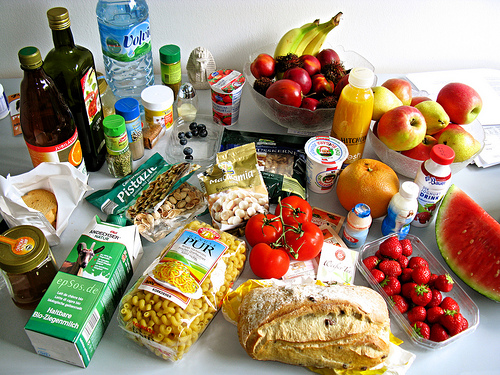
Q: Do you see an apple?
A: Yes, there is an apple.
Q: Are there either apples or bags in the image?
A: Yes, there is an apple.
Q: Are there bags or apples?
A: Yes, there is an apple.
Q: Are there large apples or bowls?
A: Yes, there is a large apple.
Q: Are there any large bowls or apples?
A: Yes, there is a large apple.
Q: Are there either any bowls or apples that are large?
A: Yes, the apple is large.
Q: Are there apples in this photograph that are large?
A: Yes, there is a large apple.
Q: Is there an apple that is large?
A: Yes, there is an apple that is large.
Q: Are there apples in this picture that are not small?
A: Yes, there is a large apple.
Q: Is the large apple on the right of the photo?
A: Yes, the apple is on the right of the image.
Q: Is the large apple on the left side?
A: No, the apple is on the right of the image.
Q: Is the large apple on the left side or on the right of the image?
A: The apple is on the right of the image.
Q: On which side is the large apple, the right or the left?
A: The apple is on the right of the image.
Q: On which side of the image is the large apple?
A: The apple is on the right of the image.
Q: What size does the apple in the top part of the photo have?
A: The apple has large size.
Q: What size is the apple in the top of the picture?
A: The apple is large.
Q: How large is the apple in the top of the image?
A: The apple is large.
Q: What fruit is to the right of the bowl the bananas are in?
A: The fruit is an apple.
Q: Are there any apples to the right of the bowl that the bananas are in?
A: Yes, there is an apple to the right of the bowl.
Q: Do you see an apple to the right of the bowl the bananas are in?
A: Yes, there is an apple to the right of the bowl.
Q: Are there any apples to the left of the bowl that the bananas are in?
A: No, the apple is to the right of the bowl.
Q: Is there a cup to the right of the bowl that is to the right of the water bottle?
A: No, there is an apple to the right of the bowl.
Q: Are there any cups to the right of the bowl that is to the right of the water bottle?
A: No, there is an apple to the right of the bowl.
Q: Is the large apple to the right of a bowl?
A: Yes, the apple is to the right of a bowl.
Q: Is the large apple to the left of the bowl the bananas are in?
A: No, the apple is to the right of the bowl.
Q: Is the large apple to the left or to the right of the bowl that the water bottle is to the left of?
A: The apple is to the right of the bowl.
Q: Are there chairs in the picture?
A: No, there are no chairs.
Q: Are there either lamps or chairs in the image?
A: No, there are no chairs or lamps.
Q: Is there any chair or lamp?
A: No, there are no chairs or lamps.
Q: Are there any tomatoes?
A: Yes, there are tomatoes.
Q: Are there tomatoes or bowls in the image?
A: Yes, there are tomatoes.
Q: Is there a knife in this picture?
A: No, there are no knives.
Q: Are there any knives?
A: No, there are no knives.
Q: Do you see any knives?
A: No, there are no knives.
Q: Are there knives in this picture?
A: No, there are no knives.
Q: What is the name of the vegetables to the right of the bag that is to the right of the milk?
A: The vegetables are tomatoes.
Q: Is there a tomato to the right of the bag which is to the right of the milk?
A: Yes, there are tomatoes to the right of the bag.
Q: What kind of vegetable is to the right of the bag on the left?
A: The vegetables are tomatoes.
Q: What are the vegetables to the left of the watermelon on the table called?
A: The vegetables are tomatoes.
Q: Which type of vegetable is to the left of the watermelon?
A: The vegetables are tomatoes.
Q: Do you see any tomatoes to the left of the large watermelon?
A: Yes, there are tomatoes to the left of the watermelon.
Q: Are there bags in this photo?
A: Yes, there is a bag.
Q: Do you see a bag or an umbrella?
A: Yes, there is a bag.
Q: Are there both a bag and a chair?
A: No, there is a bag but no chairs.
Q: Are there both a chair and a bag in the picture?
A: No, there is a bag but no chairs.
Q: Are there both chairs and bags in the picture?
A: No, there is a bag but no chairs.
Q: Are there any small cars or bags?
A: Yes, there is a small bag.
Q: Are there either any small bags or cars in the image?
A: Yes, there is a small bag.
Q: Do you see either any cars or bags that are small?
A: Yes, the bag is small.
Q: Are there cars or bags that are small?
A: Yes, the bag is small.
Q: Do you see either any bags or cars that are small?
A: Yes, the bag is small.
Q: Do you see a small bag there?
A: Yes, there is a small bag.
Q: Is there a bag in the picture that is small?
A: Yes, there is a bag that is small.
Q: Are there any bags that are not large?
A: Yes, there is a small bag.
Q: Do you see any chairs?
A: No, there are no chairs.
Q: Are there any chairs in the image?
A: No, there are no chairs.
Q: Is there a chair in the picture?
A: No, there are no chairs.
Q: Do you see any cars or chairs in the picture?
A: No, there are no chairs or cars.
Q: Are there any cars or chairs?
A: No, there are no chairs or cars.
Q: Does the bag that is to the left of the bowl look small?
A: Yes, the bag is small.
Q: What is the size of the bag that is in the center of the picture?
A: The bag is small.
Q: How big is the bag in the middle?
A: The bag is small.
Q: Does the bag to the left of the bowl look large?
A: No, the bag is small.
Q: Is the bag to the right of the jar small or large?
A: The bag is small.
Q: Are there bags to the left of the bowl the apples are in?
A: Yes, there is a bag to the left of the bowl.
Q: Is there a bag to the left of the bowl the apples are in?
A: Yes, there is a bag to the left of the bowl.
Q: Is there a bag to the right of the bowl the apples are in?
A: No, the bag is to the left of the bowl.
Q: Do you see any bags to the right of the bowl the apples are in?
A: No, the bag is to the left of the bowl.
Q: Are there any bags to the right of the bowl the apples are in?
A: No, the bag is to the left of the bowl.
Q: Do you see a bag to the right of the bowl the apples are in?
A: No, the bag is to the left of the bowl.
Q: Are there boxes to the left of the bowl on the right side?
A: No, there is a bag to the left of the bowl.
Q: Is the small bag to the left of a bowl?
A: Yes, the bag is to the left of a bowl.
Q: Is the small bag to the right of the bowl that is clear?
A: No, the bag is to the left of the bowl.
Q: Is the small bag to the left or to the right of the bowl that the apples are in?
A: The bag is to the left of the bowl.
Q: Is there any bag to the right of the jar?
A: Yes, there is a bag to the right of the jar.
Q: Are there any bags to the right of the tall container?
A: Yes, there is a bag to the right of the jar.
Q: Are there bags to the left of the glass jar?
A: No, the bag is to the right of the jar.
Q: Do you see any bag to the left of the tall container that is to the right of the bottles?
A: No, the bag is to the right of the jar.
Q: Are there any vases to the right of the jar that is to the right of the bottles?
A: No, there is a bag to the right of the jar.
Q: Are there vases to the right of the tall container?
A: No, there is a bag to the right of the jar.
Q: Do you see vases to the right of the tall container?
A: No, there is a bag to the right of the jar.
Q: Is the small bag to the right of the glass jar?
A: Yes, the bag is to the right of the jar.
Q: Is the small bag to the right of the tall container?
A: Yes, the bag is to the right of the jar.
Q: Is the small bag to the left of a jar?
A: No, the bag is to the right of a jar.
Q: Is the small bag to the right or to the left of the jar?
A: The bag is to the right of the jar.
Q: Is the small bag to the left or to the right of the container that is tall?
A: The bag is to the right of the jar.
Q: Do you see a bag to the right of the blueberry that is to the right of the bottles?
A: Yes, there is a bag to the right of the blueberry.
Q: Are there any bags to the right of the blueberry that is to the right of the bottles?
A: Yes, there is a bag to the right of the blueberry.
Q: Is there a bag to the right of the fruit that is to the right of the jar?
A: Yes, there is a bag to the right of the blueberry.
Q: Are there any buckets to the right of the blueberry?
A: No, there is a bag to the right of the blueberry.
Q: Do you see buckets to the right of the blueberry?
A: No, there is a bag to the right of the blueberry.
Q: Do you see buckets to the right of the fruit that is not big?
A: No, there is a bag to the right of the blueberry.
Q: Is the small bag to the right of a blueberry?
A: Yes, the bag is to the right of a blueberry.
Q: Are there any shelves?
A: No, there are no shelves.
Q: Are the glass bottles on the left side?
A: Yes, the bottles are on the left of the image.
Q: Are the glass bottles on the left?
A: Yes, the bottles are on the left of the image.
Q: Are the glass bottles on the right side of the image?
A: No, the bottles are on the left of the image.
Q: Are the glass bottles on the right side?
A: No, the bottles are on the left of the image.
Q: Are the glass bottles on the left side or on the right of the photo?
A: The bottles are on the left of the image.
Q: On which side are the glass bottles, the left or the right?
A: The bottles are on the left of the image.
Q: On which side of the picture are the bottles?
A: The bottles are on the left of the image.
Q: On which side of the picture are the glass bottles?
A: The bottles are on the left of the image.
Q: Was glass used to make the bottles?
A: Yes, the bottles are made of glass.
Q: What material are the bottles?
A: The bottles are made of glass.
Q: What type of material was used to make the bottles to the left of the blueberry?
A: The bottles are made of glass.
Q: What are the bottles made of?
A: The bottles are made of glass.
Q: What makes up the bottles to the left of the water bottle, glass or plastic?
A: The bottles are made of glass.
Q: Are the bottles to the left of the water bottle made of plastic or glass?
A: The bottles are made of glass.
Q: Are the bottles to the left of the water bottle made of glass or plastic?
A: The bottles are made of glass.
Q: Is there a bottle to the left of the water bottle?
A: Yes, there are bottles to the left of the water bottle.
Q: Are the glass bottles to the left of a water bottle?
A: Yes, the bottles are to the left of a water bottle.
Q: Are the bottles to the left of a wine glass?
A: No, the bottles are to the left of a water bottle.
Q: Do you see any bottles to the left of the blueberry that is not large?
A: Yes, there are bottles to the left of the blueberry.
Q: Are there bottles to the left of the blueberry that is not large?
A: Yes, there are bottles to the left of the blueberry.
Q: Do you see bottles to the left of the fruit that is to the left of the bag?
A: Yes, there are bottles to the left of the blueberry.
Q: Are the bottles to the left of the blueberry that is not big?
A: Yes, the bottles are to the left of the blueberry.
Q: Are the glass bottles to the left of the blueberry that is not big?
A: Yes, the bottles are to the left of the blueberry.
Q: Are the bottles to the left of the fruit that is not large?
A: Yes, the bottles are to the left of the blueberry.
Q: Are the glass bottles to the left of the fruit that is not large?
A: Yes, the bottles are to the left of the blueberry.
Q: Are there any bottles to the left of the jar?
A: Yes, there are bottles to the left of the jar.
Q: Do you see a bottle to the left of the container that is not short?
A: Yes, there are bottles to the left of the jar.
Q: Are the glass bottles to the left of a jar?
A: Yes, the bottles are to the left of a jar.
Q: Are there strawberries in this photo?
A: Yes, there is a strawberry.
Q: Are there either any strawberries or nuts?
A: Yes, there is a strawberry.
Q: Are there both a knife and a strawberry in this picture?
A: No, there is a strawberry but no knives.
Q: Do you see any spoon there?
A: No, there are no spoons.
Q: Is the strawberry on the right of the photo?
A: Yes, the strawberry is on the right of the image.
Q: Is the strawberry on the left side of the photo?
A: No, the strawberry is on the right of the image.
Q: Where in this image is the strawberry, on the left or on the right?
A: The strawberry is on the right of the image.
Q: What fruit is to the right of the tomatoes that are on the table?
A: The fruit is a strawberry.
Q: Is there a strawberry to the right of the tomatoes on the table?
A: Yes, there is a strawberry to the right of the tomatoes.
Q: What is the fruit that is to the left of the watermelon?
A: The fruit is a strawberry.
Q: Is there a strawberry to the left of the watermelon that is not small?
A: Yes, there is a strawberry to the left of the watermelon.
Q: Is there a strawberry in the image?
A: Yes, there is a strawberry.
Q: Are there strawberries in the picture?
A: Yes, there is a strawberry.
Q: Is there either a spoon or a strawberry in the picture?
A: Yes, there is a strawberry.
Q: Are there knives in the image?
A: No, there are no knives.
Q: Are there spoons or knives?
A: No, there are no knives or spoons.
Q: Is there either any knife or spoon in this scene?
A: No, there are no knives or spoons.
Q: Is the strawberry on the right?
A: Yes, the strawberry is on the right of the image.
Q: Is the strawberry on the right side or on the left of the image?
A: The strawberry is on the right of the image.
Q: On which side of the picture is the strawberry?
A: The strawberry is on the right of the image.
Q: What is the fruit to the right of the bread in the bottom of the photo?
A: The fruit is a strawberry.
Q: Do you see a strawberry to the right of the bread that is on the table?
A: Yes, there is a strawberry to the right of the bread.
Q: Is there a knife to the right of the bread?
A: No, there is a strawberry to the right of the bread.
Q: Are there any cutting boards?
A: No, there are no cutting boards.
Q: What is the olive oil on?
A: The olive oil is on the table.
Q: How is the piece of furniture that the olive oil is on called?
A: The piece of furniture is a table.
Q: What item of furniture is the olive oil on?
A: The olive oil is on the table.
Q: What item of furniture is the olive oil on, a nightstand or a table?
A: The olive oil is on a table.